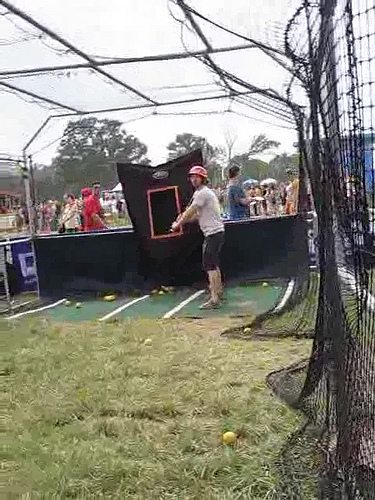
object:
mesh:
[185, 1, 375, 500]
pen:
[3, 14, 371, 494]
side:
[291, 76, 368, 434]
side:
[1, 91, 39, 322]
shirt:
[191, 185, 224, 238]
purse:
[58, 223, 65, 233]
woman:
[60, 192, 75, 230]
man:
[169, 165, 225, 311]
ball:
[223, 431, 236, 446]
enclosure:
[1, 0, 374, 498]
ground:
[18, 290, 301, 327]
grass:
[87, 335, 167, 433]